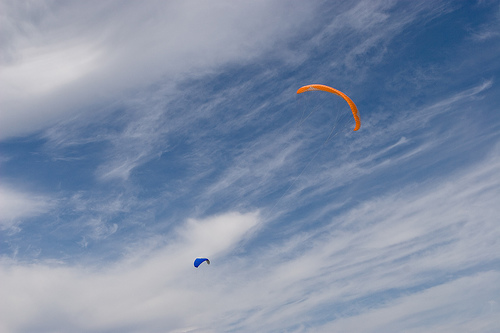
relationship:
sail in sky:
[193, 257, 210, 267] [0, 5, 496, 328]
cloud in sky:
[4, 208, 263, 332] [0, 5, 496, 328]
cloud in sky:
[309, 264, 498, 331] [0, 5, 496, 328]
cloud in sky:
[1, 0, 321, 145] [0, 5, 496, 328]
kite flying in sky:
[296, 83, 361, 132] [0, 5, 496, 328]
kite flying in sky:
[185, 248, 215, 270] [0, 5, 496, 328]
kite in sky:
[295, 73, 370, 136] [219, 117, 346, 233]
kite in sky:
[194, 257, 211, 268] [219, 117, 346, 233]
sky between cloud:
[0, 5, 496, 328] [0, 194, 270, 331]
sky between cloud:
[0, 5, 496, 328] [1, 0, 321, 145]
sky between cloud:
[0, 5, 496, 328] [0, 180, 60, 235]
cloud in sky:
[4, 180, 49, 215] [17, 73, 221, 244]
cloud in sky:
[124, 209, 259, 282] [0, 5, 496, 328]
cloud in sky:
[64, 190, 131, 248] [0, 5, 496, 328]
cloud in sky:
[4, 180, 49, 215] [0, 5, 496, 328]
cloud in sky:
[357, 82, 492, 155] [0, 5, 496, 328]